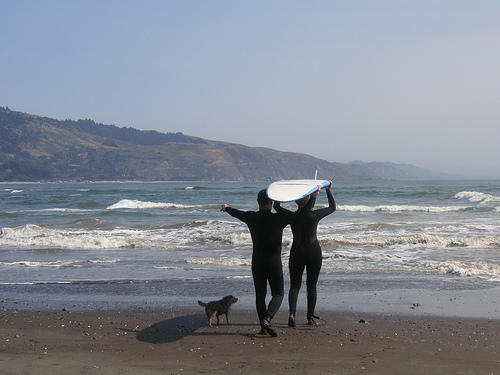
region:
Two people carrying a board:
[315, 181, 332, 191]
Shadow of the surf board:
[164, 322, 185, 329]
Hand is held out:
[219, 203, 227, 210]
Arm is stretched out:
[230, 209, 250, 217]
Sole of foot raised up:
[262, 322, 267, 329]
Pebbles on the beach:
[60, 320, 77, 327]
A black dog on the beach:
[205, 299, 229, 313]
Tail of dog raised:
[198, 299, 207, 307]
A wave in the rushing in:
[459, 192, 485, 199]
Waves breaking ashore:
[30, 232, 70, 245]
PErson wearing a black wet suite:
[215, 183, 286, 361]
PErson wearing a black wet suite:
[278, 177, 330, 334]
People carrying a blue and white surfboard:
[225, 157, 340, 372]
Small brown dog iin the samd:
[188, 286, 238, 333]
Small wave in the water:
[21, 214, 112, 266]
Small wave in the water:
[109, 206, 179, 252]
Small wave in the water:
[103, 186, 184, 226]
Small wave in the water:
[390, 188, 462, 227]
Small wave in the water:
[348, 231, 438, 278]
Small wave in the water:
[406, 254, 489, 291]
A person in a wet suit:
[218, 185, 318, 335]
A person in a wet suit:
[272, 183, 333, 323]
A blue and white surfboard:
[267, 168, 332, 203]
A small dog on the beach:
[198, 288, 243, 325]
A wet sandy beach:
[3, 277, 497, 372]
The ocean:
[2, 174, 496, 299]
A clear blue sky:
[0, 0, 499, 173]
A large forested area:
[63, 114, 199, 148]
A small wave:
[182, 183, 216, 191]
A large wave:
[450, 185, 499, 210]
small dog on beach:
[198, 295, 250, 326]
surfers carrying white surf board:
[202, 151, 353, 343]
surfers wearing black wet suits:
[232, 151, 346, 346]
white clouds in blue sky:
[12, 18, 56, 66]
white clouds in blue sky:
[52, 18, 99, 90]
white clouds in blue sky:
[130, 6, 188, 97]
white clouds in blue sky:
[192, 38, 239, 139]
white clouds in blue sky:
[245, 41, 290, 128]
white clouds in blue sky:
[278, 29, 329, 130]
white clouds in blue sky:
[327, 39, 364, 141]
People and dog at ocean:
[12, 37, 463, 372]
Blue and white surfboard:
[260, 166, 334, 210]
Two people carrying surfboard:
[236, 151, 367, 341]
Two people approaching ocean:
[221, 136, 361, 353]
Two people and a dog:
[168, 159, 347, 340]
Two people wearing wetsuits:
[210, 171, 373, 340]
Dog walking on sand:
[190, 288, 242, 333]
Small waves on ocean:
[4, 163, 494, 287]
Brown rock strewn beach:
[2, 283, 498, 370]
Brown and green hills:
[2, 86, 408, 186]